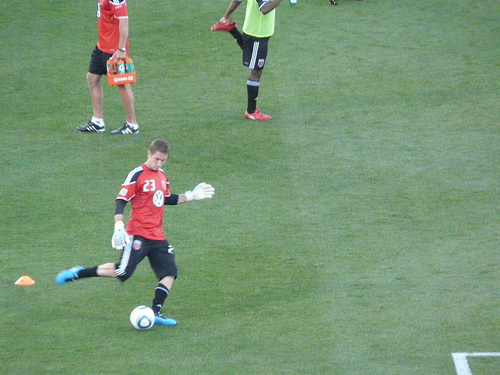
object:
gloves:
[184, 182, 214, 202]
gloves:
[110, 220, 132, 251]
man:
[54, 139, 215, 327]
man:
[209, 0, 284, 122]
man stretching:
[209, 0, 283, 122]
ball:
[128, 303, 155, 330]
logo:
[152, 190, 166, 207]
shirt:
[114, 164, 173, 242]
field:
[0, 0, 499, 375]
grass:
[0, 0, 499, 375]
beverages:
[123, 54, 135, 74]